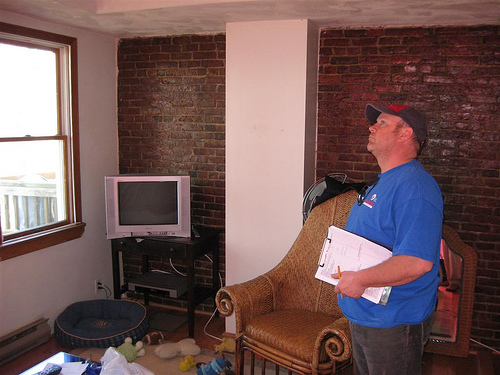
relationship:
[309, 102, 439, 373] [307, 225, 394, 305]
man holding clipboard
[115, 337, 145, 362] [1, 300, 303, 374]
toy on floor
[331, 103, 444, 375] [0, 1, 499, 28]
man looking at ceiling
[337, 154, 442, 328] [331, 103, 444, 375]
shirt worn by man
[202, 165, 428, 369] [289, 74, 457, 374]
chair next to man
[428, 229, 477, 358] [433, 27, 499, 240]
mirror propped against wall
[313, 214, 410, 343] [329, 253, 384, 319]
clipboard in hand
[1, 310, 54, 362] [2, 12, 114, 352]
heater on wall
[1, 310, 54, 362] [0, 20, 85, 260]
heater under window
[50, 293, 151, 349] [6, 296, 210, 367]
bed in floor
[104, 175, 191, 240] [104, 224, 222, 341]
television on stand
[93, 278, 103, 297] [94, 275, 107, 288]
electrical outlet with plug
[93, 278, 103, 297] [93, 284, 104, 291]
electrical outlet with plug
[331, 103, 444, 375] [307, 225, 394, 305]
man holding clipboard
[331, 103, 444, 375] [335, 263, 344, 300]
man holding pencil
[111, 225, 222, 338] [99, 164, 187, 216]
stand holding tv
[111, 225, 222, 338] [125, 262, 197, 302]
stand holding unit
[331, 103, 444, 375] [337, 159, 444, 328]
man wearing shirt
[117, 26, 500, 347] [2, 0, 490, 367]
wall of room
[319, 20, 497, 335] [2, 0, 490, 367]
wall of room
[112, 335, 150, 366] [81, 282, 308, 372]
toy all over floor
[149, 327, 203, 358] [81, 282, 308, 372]
toy all over floor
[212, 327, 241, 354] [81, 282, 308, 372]
toy all over floor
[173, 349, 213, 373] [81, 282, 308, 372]
toy all over floor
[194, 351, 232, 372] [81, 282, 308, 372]
toy all over floor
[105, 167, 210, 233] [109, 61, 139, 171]
television in a corner